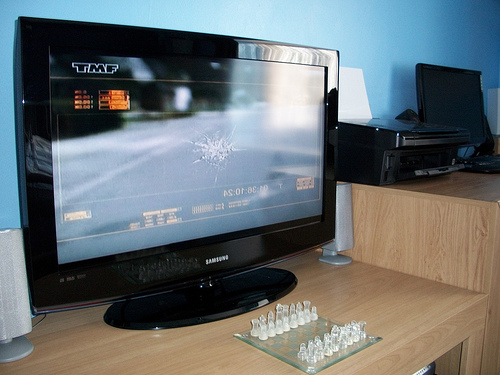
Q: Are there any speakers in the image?
A: Yes, there is a speaker.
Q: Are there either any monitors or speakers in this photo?
A: Yes, there is a speaker.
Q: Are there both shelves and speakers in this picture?
A: No, there is a speaker but no shelves.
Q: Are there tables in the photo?
A: Yes, there is a table.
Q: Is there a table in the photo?
A: Yes, there is a table.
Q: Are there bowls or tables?
A: Yes, there is a table.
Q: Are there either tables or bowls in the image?
A: Yes, there is a table.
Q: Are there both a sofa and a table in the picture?
A: No, there is a table but no sofas.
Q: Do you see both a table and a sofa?
A: No, there is a table but no sofas.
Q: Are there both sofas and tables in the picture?
A: No, there is a table but no sofas.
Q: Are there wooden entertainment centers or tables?
A: Yes, there is a wood table.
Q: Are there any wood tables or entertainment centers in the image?
A: Yes, there is a wood table.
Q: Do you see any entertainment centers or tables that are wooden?
A: Yes, the table is wooden.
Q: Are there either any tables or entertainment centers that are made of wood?
A: Yes, the table is made of wood.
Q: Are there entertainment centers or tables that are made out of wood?
A: Yes, the table is made of wood.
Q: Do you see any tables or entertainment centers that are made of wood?
A: Yes, the table is made of wood.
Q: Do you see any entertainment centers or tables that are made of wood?
A: Yes, the table is made of wood.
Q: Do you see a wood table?
A: Yes, there is a table that is made of wood.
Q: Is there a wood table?
A: Yes, there is a table that is made of wood.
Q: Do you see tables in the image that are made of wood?
A: Yes, there is a table that is made of wood.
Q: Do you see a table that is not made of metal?
A: Yes, there is a table that is made of wood.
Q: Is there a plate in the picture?
A: No, there are no plates.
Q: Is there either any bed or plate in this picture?
A: No, there are no plates or beds.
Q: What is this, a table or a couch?
A: This is a table.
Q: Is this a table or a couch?
A: This is a table.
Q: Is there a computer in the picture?
A: Yes, there is a computer.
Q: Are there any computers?
A: Yes, there is a computer.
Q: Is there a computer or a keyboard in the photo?
A: Yes, there is a computer.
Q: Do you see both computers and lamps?
A: No, there is a computer but no lamps.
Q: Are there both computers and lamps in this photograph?
A: No, there is a computer but no lamps.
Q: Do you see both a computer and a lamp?
A: No, there is a computer but no lamps.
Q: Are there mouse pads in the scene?
A: No, there are no mouse pads.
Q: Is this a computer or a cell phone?
A: This is a computer.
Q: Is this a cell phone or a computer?
A: This is a computer.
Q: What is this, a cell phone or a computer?
A: This is a computer.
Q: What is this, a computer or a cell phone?
A: This is a computer.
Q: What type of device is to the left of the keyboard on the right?
A: The device is a computer.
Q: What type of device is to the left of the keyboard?
A: The device is a computer.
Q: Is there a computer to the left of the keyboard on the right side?
A: Yes, there is a computer to the left of the keyboard.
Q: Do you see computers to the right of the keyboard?
A: No, the computer is to the left of the keyboard.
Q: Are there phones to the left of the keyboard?
A: No, there is a computer to the left of the keyboard.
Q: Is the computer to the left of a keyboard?
A: Yes, the computer is to the left of a keyboard.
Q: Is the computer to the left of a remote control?
A: No, the computer is to the left of a keyboard.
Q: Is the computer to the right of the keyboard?
A: No, the computer is to the left of the keyboard.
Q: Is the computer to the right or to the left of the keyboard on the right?
A: The computer is to the left of the keyboard.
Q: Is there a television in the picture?
A: Yes, there is a television.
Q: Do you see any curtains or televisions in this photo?
A: Yes, there is a television.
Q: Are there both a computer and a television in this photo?
A: Yes, there are both a television and a computer.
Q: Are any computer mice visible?
A: No, there are no computer mice.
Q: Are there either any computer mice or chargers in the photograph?
A: No, there are no computer mice or chargers.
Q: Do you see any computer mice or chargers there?
A: No, there are no computer mice or chargers.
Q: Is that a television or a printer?
A: That is a television.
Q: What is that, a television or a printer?
A: That is a television.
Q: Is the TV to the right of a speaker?
A: Yes, the TV is to the right of a speaker.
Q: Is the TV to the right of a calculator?
A: No, the TV is to the right of a speaker.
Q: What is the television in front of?
A: The television is in front of the wall.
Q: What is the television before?
A: The television is in front of the wall.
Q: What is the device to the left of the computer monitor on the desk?
A: The device is a television.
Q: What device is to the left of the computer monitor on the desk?
A: The device is a television.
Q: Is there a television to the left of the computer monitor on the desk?
A: Yes, there is a television to the left of the computer monitor.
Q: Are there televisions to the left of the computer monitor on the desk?
A: Yes, there is a television to the left of the computer monitor.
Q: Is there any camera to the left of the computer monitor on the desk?
A: No, there is a television to the left of the computer monitor.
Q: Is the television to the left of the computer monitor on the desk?
A: Yes, the television is to the left of the computer monitor.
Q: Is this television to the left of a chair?
A: No, the television is to the left of the computer monitor.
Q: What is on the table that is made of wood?
A: The TV is on the table.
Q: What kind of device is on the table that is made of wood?
A: The device is a television.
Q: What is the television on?
A: The television is on the table.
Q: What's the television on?
A: The television is on the table.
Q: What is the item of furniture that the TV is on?
A: The piece of furniture is a table.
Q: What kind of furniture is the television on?
A: The TV is on the table.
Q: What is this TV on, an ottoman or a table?
A: The TV is on a table.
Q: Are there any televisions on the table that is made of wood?
A: Yes, there is a television on the table.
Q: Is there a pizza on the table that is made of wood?
A: No, there is a television on the table.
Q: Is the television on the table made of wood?
A: Yes, the television is on the table.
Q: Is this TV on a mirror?
A: No, the TV is on the table.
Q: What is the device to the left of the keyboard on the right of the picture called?
A: The device is a television.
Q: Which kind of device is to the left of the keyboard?
A: The device is a television.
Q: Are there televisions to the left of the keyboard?
A: Yes, there is a television to the left of the keyboard.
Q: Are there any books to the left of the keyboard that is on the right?
A: No, there is a television to the left of the keyboard.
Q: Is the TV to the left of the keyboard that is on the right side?
A: Yes, the TV is to the left of the keyboard.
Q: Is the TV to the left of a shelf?
A: No, the TV is to the left of the keyboard.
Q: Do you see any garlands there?
A: No, there are no garlands.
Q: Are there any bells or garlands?
A: No, there are no garlands or bells.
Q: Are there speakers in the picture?
A: Yes, there is a speaker.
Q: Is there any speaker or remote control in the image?
A: Yes, there is a speaker.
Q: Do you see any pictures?
A: No, there are no pictures.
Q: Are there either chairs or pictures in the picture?
A: No, there are no pictures or chairs.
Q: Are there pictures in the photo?
A: No, there are no pictures.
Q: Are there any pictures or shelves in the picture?
A: No, there are no pictures or shelves.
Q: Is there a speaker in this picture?
A: Yes, there is a speaker.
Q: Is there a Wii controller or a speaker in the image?
A: Yes, there is a speaker.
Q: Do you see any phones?
A: No, there are no phones.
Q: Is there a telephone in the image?
A: No, there are no phones.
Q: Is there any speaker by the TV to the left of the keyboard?
A: Yes, there is a speaker by the television.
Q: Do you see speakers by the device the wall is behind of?
A: Yes, there is a speaker by the television.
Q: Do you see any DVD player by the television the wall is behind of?
A: No, there is a speaker by the television.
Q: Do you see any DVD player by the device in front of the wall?
A: No, there is a speaker by the television.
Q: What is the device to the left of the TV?
A: The device is a speaker.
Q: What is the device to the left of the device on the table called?
A: The device is a speaker.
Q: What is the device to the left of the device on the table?
A: The device is a speaker.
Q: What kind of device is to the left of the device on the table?
A: The device is a speaker.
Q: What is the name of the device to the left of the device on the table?
A: The device is a speaker.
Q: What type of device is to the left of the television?
A: The device is a speaker.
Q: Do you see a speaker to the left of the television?
A: Yes, there is a speaker to the left of the television.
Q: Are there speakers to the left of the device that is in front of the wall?
A: Yes, there is a speaker to the left of the television.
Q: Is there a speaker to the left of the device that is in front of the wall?
A: Yes, there is a speaker to the left of the television.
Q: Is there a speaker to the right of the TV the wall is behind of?
A: No, the speaker is to the left of the TV.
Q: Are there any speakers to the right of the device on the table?
A: No, the speaker is to the left of the TV.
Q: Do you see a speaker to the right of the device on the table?
A: No, the speaker is to the left of the TV.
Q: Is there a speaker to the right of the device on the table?
A: No, the speaker is to the left of the TV.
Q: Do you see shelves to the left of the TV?
A: No, there is a speaker to the left of the TV.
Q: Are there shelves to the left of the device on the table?
A: No, there is a speaker to the left of the TV.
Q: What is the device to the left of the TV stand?
A: The device is a speaker.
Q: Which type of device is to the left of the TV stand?
A: The device is a speaker.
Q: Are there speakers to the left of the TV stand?
A: Yes, there is a speaker to the left of the TV stand.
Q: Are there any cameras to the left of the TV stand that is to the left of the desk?
A: No, there is a speaker to the left of the TV stand.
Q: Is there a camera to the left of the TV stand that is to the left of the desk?
A: No, there is a speaker to the left of the TV stand.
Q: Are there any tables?
A: Yes, there is a table.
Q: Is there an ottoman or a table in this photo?
A: Yes, there is a table.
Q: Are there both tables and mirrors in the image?
A: No, there is a table but no mirrors.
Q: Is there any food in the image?
A: No, there is no food.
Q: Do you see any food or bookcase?
A: No, there are no food or bookcases.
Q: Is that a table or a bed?
A: That is a table.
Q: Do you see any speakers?
A: Yes, there is a speaker.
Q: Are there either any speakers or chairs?
A: Yes, there is a speaker.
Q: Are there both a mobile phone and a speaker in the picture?
A: No, there is a speaker but no cell phones.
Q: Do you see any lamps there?
A: No, there are no lamps.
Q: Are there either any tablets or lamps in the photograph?
A: No, there are no lamps or tablets.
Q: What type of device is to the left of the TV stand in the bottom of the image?
A: The device is a speaker.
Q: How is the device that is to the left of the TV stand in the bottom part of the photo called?
A: The device is a speaker.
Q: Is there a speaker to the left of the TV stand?
A: Yes, there is a speaker to the left of the TV stand.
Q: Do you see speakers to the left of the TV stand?
A: Yes, there is a speaker to the left of the TV stand.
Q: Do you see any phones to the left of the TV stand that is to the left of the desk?
A: No, there is a speaker to the left of the TV stand.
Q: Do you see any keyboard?
A: Yes, there is a keyboard.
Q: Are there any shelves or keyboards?
A: Yes, there is a keyboard.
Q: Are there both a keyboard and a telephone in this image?
A: No, there is a keyboard but no phones.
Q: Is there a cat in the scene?
A: No, there are no cats.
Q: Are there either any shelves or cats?
A: No, there are no cats or shelves.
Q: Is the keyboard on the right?
A: Yes, the keyboard is on the right of the image.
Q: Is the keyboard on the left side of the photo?
A: No, the keyboard is on the right of the image.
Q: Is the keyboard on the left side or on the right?
A: The keyboard is on the right of the image.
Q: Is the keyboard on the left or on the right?
A: The keyboard is on the right of the image.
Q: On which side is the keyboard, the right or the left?
A: The keyboard is on the right of the image.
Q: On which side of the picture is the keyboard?
A: The keyboard is on the right of the image.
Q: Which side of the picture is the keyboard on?
A: The keyboard is on the right of the image.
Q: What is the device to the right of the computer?
A: The device is a keyboard.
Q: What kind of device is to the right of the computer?
A: The device is a keyboard.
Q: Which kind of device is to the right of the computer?
A: The device is a keyboard.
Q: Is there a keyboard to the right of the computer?
A: Yes, there is a keyboard to the right of the computer.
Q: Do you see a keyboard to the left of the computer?
A: No, the keyboard is to the right of the computer.